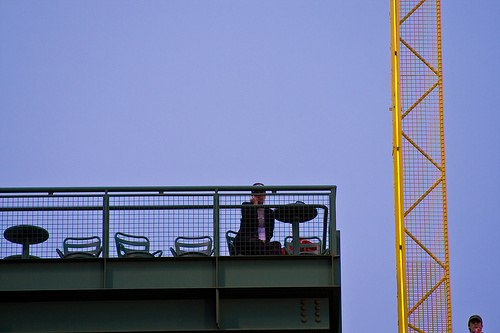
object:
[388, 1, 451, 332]
tower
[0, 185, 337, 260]
fence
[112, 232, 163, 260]
seats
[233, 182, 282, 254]
person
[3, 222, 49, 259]
table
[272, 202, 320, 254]
table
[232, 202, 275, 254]
sweater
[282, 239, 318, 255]
red object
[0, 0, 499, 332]
sky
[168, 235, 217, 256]
chair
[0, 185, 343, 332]
deck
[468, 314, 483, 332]
man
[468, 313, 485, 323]
cap